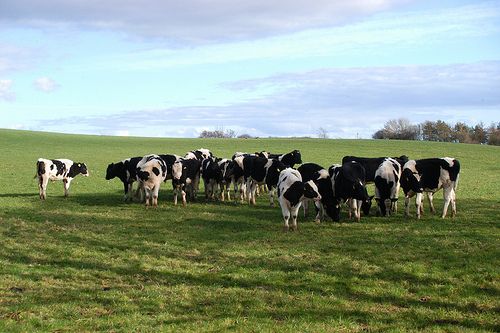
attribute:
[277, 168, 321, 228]
cow — white, black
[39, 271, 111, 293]
grass — brown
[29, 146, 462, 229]
herd — small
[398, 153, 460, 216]
cow — white, black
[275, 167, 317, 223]
cow — black, white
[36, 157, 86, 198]
cow — black, white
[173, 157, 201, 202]
cow — black, white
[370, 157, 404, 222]
cow — black, white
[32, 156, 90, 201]
cow — black, white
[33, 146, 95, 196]
cow — standing, alone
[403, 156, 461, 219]
cow — white, black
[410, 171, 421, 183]
spot — white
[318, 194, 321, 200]
nose — pink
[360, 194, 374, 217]
head — black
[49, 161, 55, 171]
spot — black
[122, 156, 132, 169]
spot — black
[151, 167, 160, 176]
spot — black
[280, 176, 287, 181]
spot — black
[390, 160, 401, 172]
spot — black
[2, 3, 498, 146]
sky — blue